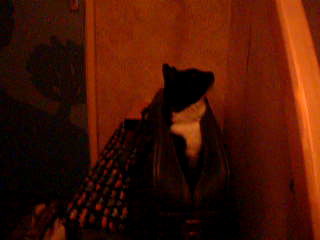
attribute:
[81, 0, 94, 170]
frame — wooden, beige, white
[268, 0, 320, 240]
rail — bannister, wooden, white, stair rail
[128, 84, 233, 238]
bag — patterned, leather, black, brown, red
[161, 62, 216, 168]
cat — black, staring, white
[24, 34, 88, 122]
tree — painted, blurry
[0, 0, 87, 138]
wall — dark, orange, white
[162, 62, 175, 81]
ear — black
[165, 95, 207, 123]
neck — white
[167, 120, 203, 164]
chest — white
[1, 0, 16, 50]
spot — dark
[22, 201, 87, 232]
items — sitting